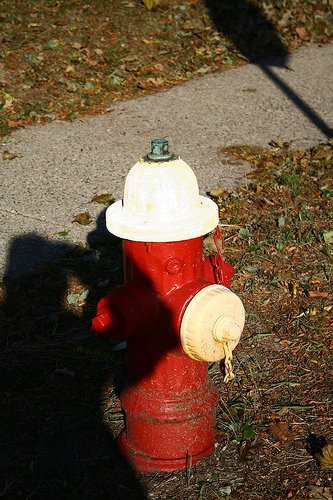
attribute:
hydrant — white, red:
[98, 136, 285, 314]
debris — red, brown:
[165, 71, 281, 147]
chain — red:
[211, 226, 224, 284]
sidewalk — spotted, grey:
[2, 41, 331, 295]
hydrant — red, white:
[59, 131, 267, 466]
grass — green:
[271, 156, 313, 195]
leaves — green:
[0, 0, 331, 138]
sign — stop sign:
[199, 0, 297, 72]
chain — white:
[212, 337, 246, 388]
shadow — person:
[14, 214, 172, 494]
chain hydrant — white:
[187, 295, 247, 391]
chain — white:
[220, 337, 237, 383]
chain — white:
[217, 331, 240, 378]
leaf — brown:
[150, 68, 163, 86]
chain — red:
[187, 229, 239, 298]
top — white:
[106, 157, 220, 243]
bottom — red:
[81, 227, 235, 466]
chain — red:
[209, 224, 229, 288]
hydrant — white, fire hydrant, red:
[92, 137, 245, 471]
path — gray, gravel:
[0, 41, 326, 300]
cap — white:
[99, 131, 226, 247]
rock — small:
[215, 483, 235, 496]